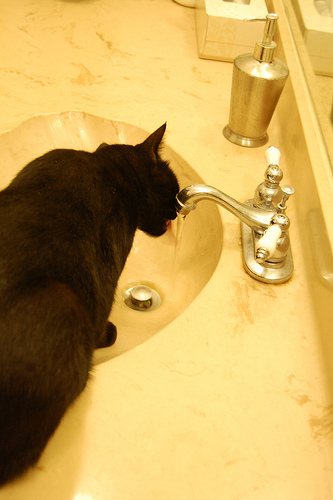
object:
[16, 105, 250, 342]
sink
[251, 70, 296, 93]
wall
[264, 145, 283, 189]
handle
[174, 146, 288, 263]
faucet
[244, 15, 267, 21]
nozzle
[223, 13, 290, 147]
dispenser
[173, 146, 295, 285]
sink faucet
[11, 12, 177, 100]
counter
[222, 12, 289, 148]
bottle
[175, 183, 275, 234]
faucet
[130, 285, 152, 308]
sink plug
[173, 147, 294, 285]
sink hardware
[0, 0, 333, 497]
countertop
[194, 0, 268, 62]
box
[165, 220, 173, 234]
tongue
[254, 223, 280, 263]
handle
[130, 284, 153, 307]
plug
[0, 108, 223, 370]
sink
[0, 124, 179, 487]
cat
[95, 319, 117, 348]
paw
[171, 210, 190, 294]
water